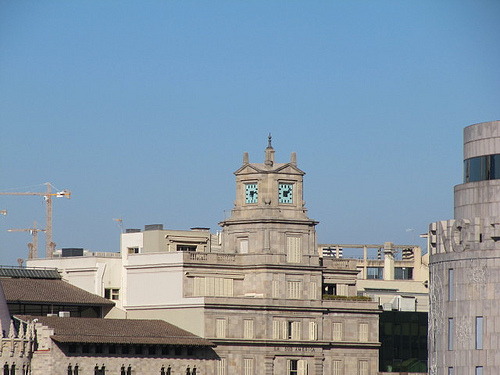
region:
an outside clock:
[147, 104, 416, 271]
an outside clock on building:
[176, 141, 336, 231]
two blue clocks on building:
[219, 139, 440, 288]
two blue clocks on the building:
[193, 112, 414, 292]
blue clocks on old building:
[189, 134, 383, 305]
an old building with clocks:
[151, 107, 436, 313]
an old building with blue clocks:
[179, 116, 368, 360]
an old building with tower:
[152, 91, 389, 361]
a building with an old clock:
[119, 100, 367, 349]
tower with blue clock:
[174, 132, 373, 368]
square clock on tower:
[275, 182, 296, 206]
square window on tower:
[284, 280, 306, 297]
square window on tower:
[278, 229, 303, 266]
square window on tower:
[331, 322, 345, 343]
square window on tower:
[353, 320, 371, 341]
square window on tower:
[238, 317, 258, 339]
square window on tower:
[239, 357, 255, 372]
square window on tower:
[330, 354, 347, 374]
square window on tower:
[357, 359, 370, 374]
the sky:
[97, 25, 347, 115]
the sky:
[74, 36, 195, 91]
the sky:
[125, 130, 185, 221]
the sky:
[56, 113, 118, 175]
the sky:
[164, 115, 204, 143]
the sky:
[72, 84, 169, 186]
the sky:
[69, 0, 243, 170]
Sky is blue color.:
[54, 33, 416, 127]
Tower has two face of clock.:
[238, 170, 308, 217]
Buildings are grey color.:
[6, 198, 488, 373]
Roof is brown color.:
[25, 278, 147, 344]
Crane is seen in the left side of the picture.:
[5, 176, 72, 262]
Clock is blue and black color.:
[242, 182, 302, 206]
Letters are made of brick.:
[419, 220, 499, 260]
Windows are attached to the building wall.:
[62, 351, 219, 373]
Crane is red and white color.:
[7, 179, 73, 254]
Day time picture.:
[30, 40, 486, 367]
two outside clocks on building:
[200, 135, 393, 275]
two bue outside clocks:
[205, 120, 382, 253]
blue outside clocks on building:
[224, 134, 349, 266]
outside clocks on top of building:
[208, 134, 337, 356]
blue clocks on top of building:
[212, 120, 357, 267]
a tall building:
[130, 135, 425, 373]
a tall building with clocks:
[133, 90, 378, 370]